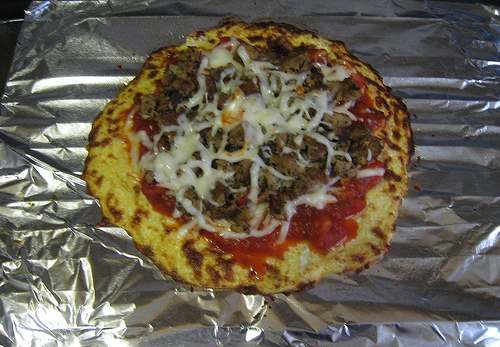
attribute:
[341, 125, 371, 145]
meat — small, balled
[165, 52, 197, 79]
meat — balled, small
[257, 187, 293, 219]
meat — balled, small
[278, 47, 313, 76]
meat — balled, small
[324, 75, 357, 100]
meat — balled, small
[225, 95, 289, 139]
cheese — melted, shredded, white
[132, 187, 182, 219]
sauce — red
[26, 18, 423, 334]
cheese pizza — mozzerella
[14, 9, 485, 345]
foil — tin, aluminum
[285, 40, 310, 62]
beef — gound 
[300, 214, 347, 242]
sauce — red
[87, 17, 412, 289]
pizza — small, home made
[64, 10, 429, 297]
pizza — whole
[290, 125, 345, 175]
gound beef — gound 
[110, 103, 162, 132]
sauce — red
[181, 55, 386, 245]
sauce — red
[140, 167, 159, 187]
gound beef — ground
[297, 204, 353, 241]
sauce — red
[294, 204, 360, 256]
sauce — red